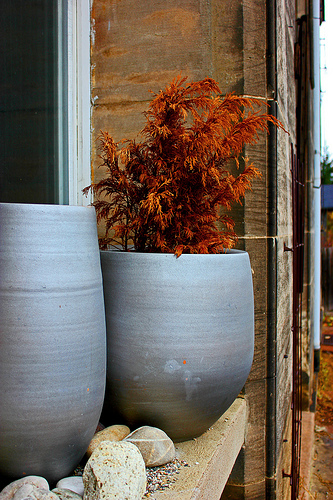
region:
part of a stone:
[117, 475, 131, 491]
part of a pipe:
[260, 432, 281, 465]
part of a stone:
[113, 438, 128, 455]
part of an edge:
[216, 422, 233, 441]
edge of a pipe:
[258, 447, 278, 484]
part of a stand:
[153, 463, 173, 481]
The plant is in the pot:
[96, 101, 277, 347]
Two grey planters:
[4, 206, 232, 418]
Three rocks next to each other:
[94, 425, 162, 498]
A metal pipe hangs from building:
[302, 4, 319, 191]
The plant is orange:
[123, 101, 241, 248]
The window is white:
[60, 3, 91, 183]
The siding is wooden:
[107, 7, 267, 83]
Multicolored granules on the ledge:
[150, 466, 187, 493]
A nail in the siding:
[281, 354, 291, 362]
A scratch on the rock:
[128, 430, 172, 447]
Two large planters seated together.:
[0, 202, 255, 475]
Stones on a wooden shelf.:
[1, 424, 202, 497]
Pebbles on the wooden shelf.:
[143, 460, 173, 491]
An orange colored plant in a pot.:
[93, 75, 276, 430]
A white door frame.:
[55, 0, 86, 196]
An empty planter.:
[1, 203, 101, 475]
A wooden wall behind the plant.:
[95, 2, 264, 241]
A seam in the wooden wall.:
[91, 89, 266, 103]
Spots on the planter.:
[139, 358, 198, 395]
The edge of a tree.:
[320, 150, 331, 185]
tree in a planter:
[129, 136, 234, 287]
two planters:
[16, 205, 235, 430]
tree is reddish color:
[129, 73, 229, 221]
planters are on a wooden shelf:
[33, 322, 290, 449]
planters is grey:
[70, 276, 144, 390]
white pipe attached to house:
[312, 242, 318, 311]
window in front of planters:
[15, 23, 54, 167]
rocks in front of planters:
[63, 418, 150, 497]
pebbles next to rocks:
[142, 460, 175, 482]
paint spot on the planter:
[177, 355, 193, 366]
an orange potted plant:
[97, 85, 283, 250]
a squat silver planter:
[101, 248, 252, 440]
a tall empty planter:
[0, 202, 104, 478]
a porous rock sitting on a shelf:
[80, 436, 144, 499]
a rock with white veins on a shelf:
[120, 424, 175, 464]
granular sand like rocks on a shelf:
[147, 464, 176, 493]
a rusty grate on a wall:
[280, 151, 307, 498]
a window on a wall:
[0, 0, 93, 203]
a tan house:
[0, 0, 318, 498]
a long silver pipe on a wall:
[310, 0, 321, 349]